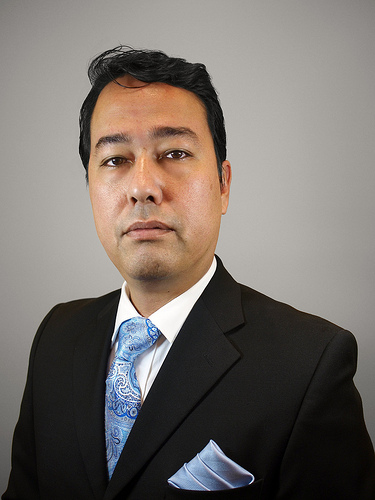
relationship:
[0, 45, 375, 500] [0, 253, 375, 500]
man wearing jacket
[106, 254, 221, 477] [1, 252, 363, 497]
shirt under suit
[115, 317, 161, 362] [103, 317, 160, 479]
knot of tie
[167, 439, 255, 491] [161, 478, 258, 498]
handkerchief placed inside pocket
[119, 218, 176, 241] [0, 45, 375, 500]
mouth belonging to man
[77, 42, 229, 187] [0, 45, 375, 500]
hair belonging to man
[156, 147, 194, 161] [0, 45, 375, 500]
eye belonging to man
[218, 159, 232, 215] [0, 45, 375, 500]
ear belonging to man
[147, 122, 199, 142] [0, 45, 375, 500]
eyebrow belonging to man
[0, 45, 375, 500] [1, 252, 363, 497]
man wearing suit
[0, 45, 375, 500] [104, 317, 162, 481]
man wearing neck tie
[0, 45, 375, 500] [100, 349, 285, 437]
man wearing jacket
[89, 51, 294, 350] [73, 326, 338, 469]
man wearing jacket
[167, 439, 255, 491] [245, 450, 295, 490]
handkerchief in pocket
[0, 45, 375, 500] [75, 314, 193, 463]
man wearing tie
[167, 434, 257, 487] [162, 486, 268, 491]
handkerchief in pocket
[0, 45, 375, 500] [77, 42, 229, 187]
man has hair